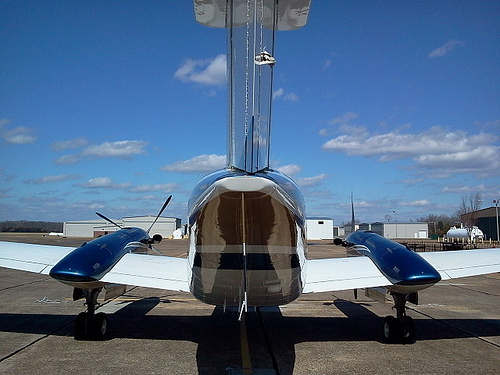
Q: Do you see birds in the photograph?
A: No, there are no birds.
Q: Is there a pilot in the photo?
A: No, there are no pilots.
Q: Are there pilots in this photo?
A: No, there are no pilots.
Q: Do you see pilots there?
A: No, there are no pilots.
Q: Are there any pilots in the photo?
A: No, there are no pilots.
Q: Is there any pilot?
A: No, there are no pilots.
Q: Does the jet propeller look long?
A: Yes, the propeller is long.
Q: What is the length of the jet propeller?
A: The propeller is long.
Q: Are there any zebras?
A: No, there are no zebras.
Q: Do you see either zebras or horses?
A: No, there are no zebras or horses.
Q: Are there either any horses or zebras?
A: No, there are no zebras or horses.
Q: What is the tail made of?
A: The tail is made of metal.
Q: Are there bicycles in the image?
A: No, there are no bicycles.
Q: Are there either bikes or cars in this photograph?
A: No, there are no bikes or cars.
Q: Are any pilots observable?
A: No, there are no pilots.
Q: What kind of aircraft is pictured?
A: The aircraft is a jet.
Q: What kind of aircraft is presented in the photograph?
A: The aircraft is a jet.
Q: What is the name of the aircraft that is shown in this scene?
A: The aircraft is a jet.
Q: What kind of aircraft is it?
A: The aircraft is a jet.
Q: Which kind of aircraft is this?
A: This is a jet.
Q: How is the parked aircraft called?
A: The aircraft is a jet.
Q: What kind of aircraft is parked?
A: The aircraft is a jet.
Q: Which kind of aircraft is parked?
A: The aircraft is a jet.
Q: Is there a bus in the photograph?
A: No, there are no buses.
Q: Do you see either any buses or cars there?
A: No, there are no buses or cars.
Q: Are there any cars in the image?
A: No, there are no cars.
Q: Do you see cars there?
A: No, there are no cars.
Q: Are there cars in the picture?
A: No, there are no cars.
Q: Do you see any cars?
A: No, there are no cars.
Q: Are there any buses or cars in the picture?
A: No, there are no cars or buses.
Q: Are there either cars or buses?
A: No, there are no cars or buses.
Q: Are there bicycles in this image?
A: No, there are no bicycles.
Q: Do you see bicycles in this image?
A: No, there are no bicycles.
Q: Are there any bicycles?
A: No, there are no bicycles.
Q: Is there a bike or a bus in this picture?
A: No, there are no bikes or buses.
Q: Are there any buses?
A: No, there are no buses.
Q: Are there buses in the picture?
A: No, there are no buses.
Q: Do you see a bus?
A: No, there are no buses.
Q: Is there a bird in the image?
A: No, there are no birds.